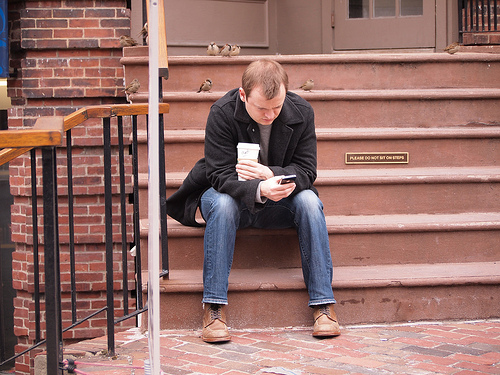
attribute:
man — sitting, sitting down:
[166, 59, 344, 343]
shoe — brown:
[201, 301, 229, 342]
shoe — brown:
[312, 303, 337, 336]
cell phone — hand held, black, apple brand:
[278, 174, 297, 190]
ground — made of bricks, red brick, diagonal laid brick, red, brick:
[33, 321, 498, 374]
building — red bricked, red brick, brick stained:
[2, 3, 498, 374]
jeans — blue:
[198, 186, 339, 307]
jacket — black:
[167, 90, 318, 224]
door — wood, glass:
[325, 1, 445, 54]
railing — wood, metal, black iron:
[1, 98, 157, 374]